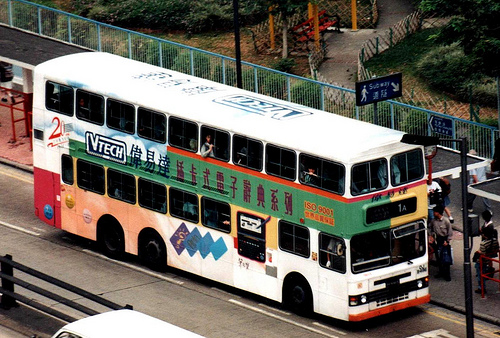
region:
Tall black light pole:
[398, 123, 485, 331]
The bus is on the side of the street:
[34, 41, 427, 331]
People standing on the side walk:
[436, 179, 490, 305]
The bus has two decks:
[33, 56, 436, 330]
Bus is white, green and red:
[33, 51, 433, 326]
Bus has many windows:
[50, 70, 425, 281]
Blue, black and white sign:
[343, 63, 420, 102]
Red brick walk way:
[1, 87, 34, 167]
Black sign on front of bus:
[343, 185, 419, 219]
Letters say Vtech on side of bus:
[76, 122, 138, 172]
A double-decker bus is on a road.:
[18, 39, 433, 336]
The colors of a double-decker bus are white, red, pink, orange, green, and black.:
[22, 39, 444, 335]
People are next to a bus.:
[409, 161, 499, 298]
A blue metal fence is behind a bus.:
[2, 1, 499, 168]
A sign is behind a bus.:
[339, 62, 406, 139]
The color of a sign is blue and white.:
[344, 68, 416, 133]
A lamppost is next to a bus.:
[393, 123, 498, 337]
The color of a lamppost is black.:
[397, 124, 484, 336]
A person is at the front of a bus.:
[340, 135, 430, 207]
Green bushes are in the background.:
[2, 1, 499, 161]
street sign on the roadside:
[346, 75, 416, 102]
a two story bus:
[28, 40, 438, 327]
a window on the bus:
[259, 140, 298, 185]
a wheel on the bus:
[278, 272, 320, 323]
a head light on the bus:
[411, 274, 435, 296]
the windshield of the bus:
[344, 215, 430, 276]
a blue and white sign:
[343, 70, 410, 109]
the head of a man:
[430, 202, 447, 221]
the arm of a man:
[442, 217, 457, 243]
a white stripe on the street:
[0, 217, 41, 239]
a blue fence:
[0, 0, 499, 162]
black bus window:
[73, 155, 106, 197]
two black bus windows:
[57, 154, 107, 197]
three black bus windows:
[54, 153, 139, 205]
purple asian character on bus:
[279, 187, 297, 216]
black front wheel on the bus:
[273, 273, 318, 318]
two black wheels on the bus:
[93, 210, 168, 275]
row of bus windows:
[51, 151, 311, 270]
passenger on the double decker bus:
[197, 126, 229, 163]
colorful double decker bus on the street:
[28, 49, 442, 327]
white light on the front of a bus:
[359, 295, 368, 302]